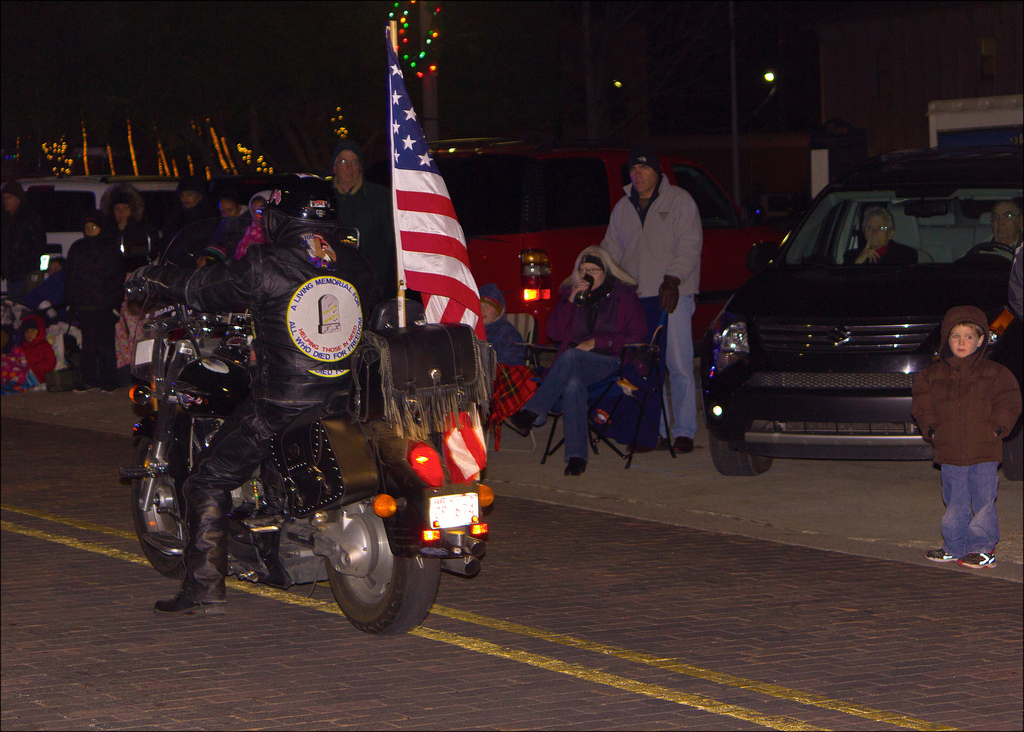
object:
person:
[599, 146, 703, 453]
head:
[630, 151, 663, 193]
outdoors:
[0, 0, 1024, 732]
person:
[506, 246, 651, 477]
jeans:
[520, 348, 622, 463]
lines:
[406, 602, 975, 732]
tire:
[321, 498, 441, 637]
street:
[520, 536, 752, 624]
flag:
[383, 25, 485, 341]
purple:
[584, 271, 616, 335]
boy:
[911, 305, 1024, 569]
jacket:
[911, 305, 1024, 465]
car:
[699, 146, 1024, 482]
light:
[406, 441, 442, 487]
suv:
[429, 139, 787, 346]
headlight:
[523, 288, 537, 300]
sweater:
[600, 173, 704, 299]